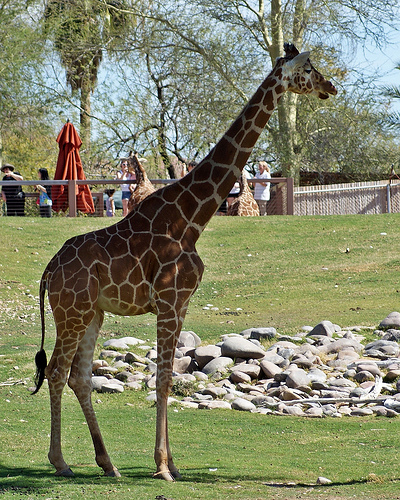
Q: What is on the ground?
A: Rocks.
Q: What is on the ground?
A: Rocks.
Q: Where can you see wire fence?
A: Near the tree.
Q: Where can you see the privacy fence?
A: Behind the wire fence.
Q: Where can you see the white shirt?
A: Next to the wooden fence.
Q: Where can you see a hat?
A: On man's head.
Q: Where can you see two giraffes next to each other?
A: Behind the giraffe standing alone.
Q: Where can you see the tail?
A: Behind giraffe.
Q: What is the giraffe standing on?
A: Standing on grass.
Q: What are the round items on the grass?
A: They are rocks.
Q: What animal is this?
A: Giraffe.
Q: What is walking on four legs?
A: Giraffe.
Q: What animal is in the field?
A: Giraffe.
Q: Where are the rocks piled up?
A: Next to the giraffe.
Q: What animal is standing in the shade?
A: A giraffe.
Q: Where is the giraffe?
A: In the zoo.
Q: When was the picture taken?
A: Daytime.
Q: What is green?
A: Grass.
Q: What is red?
A: Umbrella.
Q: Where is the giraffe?
A: In the middle of the picture.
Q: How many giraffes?
A: One.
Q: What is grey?
A: Piles of rocks.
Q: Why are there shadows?
A: Sunshine.